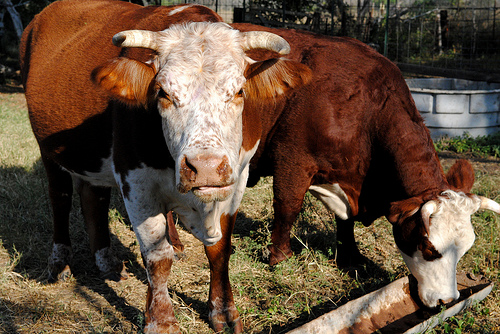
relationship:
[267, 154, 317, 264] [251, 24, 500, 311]
leg of cow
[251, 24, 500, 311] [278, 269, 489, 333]
cow eating from trough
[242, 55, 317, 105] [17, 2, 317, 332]
ear of cow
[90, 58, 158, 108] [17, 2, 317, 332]
ear of a cow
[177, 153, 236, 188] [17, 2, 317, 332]
nose of a cow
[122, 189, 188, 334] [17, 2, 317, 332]
leg of a cow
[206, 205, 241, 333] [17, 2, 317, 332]
leg on a cow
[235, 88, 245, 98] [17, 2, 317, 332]
eyes of a cow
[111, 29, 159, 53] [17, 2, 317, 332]
horn on a cow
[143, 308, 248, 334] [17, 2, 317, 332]
hooves on cow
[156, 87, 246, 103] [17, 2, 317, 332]
eyes od cow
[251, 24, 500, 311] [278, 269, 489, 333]
cow eating from a trough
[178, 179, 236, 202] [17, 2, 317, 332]
mouth of a cow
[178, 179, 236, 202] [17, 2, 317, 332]
mouth on a cow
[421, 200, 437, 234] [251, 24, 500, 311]
horn of a cow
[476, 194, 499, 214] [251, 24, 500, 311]
horn of a cow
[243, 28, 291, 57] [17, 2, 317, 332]
horn on a cow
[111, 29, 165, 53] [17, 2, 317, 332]
horn of a cow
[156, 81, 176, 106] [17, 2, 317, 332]
eye of a cow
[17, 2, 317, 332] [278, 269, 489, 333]
cow stands at trough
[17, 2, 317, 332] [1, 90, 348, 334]
cow in grass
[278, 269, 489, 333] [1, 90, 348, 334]
trough in grass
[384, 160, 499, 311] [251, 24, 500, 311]
head of a cow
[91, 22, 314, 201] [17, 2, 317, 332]
head of a cow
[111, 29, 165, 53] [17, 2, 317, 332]
horn of cow